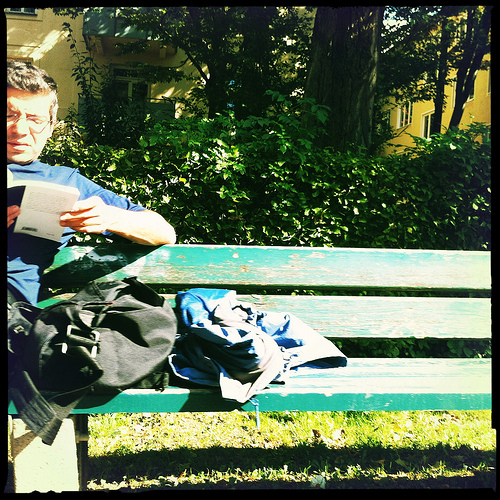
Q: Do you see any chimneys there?
A: No, there are no chimneys.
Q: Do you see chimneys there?
A: No, there are no chimneys.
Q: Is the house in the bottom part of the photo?
A: No, the house is in the top of the image.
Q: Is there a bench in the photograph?
A: Yes, there is a bench.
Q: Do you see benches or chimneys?
A: Yes, there is a bench.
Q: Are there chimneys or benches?
A: Yes, there is a bench.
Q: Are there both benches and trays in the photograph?
A: No, there is a bench but no trays.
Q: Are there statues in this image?
A: No, there are no statues.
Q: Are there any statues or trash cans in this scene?
A: No, there are no statues or trash cans.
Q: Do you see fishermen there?
A: No, there are no fishermen.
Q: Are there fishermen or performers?
A: No, there are no fishermen or performers.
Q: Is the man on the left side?
A: Yes, the man is on the left of the image.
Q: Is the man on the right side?
A: No, the man is on the left of the image.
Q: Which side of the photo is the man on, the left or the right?
A: The man is on the left of the image.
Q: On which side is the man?
A: The man is on the left of the image.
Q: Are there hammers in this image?
A: No, there are no hammers.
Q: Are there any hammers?
A: No, there are no hammers.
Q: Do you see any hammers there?
A: No, there are no hammers.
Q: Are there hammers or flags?
A: No, there are no hammers or flags.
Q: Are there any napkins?
A: No, there are no napkins.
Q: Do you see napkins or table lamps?
A: No, there are no napkins or table lamps.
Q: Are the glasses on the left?
A: Yes, the glasses are on the left of the image.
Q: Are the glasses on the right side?
A: No, the glasses are on the left of the image.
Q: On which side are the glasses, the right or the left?
A: The glasses are on the left of the image.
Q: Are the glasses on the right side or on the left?
A: The glasses are on the left of the image.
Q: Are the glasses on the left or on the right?
A: The glasses are on the left of the image.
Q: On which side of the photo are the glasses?
A: The glasses are on the left of the image.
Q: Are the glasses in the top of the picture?
A: Yes, the glasses are in the top of the image.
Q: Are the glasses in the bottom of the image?
A: No, the glasses are in the top of the image.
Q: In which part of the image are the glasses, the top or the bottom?
A: The glasses are in the top of the image.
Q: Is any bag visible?
A: Yes, there is a bag.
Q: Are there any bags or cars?
A: Yes, there is a bag.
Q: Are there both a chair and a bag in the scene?
A: No, there is a bag but no chairs.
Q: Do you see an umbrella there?
A: No, there are no umbrellas.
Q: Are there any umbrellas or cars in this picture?
A: No, there are no umbrellas or cars.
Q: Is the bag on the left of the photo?
A: Yes, the bag is on the left of the image.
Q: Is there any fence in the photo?
A: No, there are no fences.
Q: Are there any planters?
A: No, there are no planters.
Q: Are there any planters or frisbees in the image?
A: No, there are no planters or frisbees.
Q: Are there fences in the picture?
A: No, there are no fences.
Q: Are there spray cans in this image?
A: No, there are no spray cans.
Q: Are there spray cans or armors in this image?
A: No, there are no spray cans or armors.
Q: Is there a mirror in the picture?
A: No, there are no mirrors.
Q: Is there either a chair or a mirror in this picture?
A: No, there are no mirrors or chairs.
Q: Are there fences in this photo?
A: No, there are no fences.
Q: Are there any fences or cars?
A: No, there are no fences or cars.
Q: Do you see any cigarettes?
A: No, there are no cigarettes.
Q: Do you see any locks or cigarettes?
A: No, there are no cigarettes or locks.